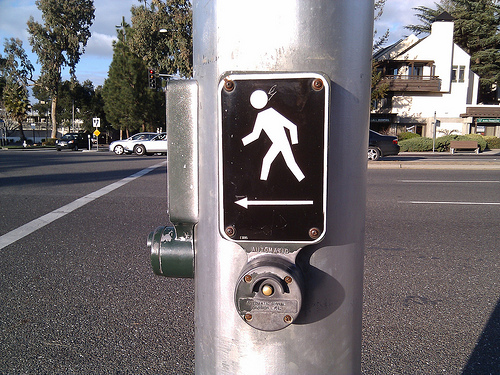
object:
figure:
[241, 89, 306, 182]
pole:
[190, 0, 370, 375]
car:
[55, 130, 93, 151]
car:
[109, 132, 158, 156]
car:
[124, 132, 167, 155]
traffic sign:
[94, 130, 101, 137]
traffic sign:
[93, 117, 101, 127]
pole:
[96, 116, 99, 151]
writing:
[268, 84, 278, 101]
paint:
[2, 223, 38, 243]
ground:
[0, 160, 139, 368]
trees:
[25, 0, 93, 137]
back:
[14, 5, 484, 162]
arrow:
[233, 196, 313, 209]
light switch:
[147, 225, 194, 278]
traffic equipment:
[148, 70, 333, 331]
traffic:
[52, 108, 162, 171]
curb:
[369, 160, 500, 168]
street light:
[159, 28, 168, 32]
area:
[0, 156, 156, 205]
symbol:
[241, 89, 306, 182]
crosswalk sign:
[217, 73, 330, 243]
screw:
[311, 74, 329, 94]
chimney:
[429, 20, 454, 93]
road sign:
[88, 111, 112, 127]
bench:
[450, 140, 480, 154]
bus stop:
[402, 129, 485, 166]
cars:
[368, 129, 400, 161]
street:
[374, 158, 496, 365]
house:
[373, 11, 481, 138]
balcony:
[376, 60, 444, 97]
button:
[261, 284, 272, 296]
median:
[396, 179, 500, 184]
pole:
[88, 134, 91, 150]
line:
[0, 159, 167, 249]